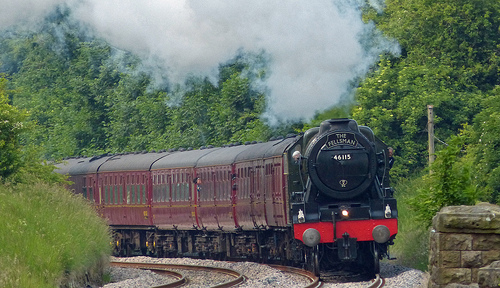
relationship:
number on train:
[334, 154, 339, 161] [42, 116, 397, 278]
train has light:
[42, 116, 397, 278] [337, 205, 353, 221]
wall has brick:
[428, 202, 500, 288] [482, 249, 499, 264]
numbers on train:
[329, 152, 357, 160] [68, 97, 420, 270]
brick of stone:
[438, 232, 473, 252] [433, 205, 499, 235]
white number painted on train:
[331, 149, 340, 161] [42, 116, 397, 278]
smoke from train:
[2, 0, 402, 130] [42, 116, 397, 278]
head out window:
[187, 170, 202, 185] [267, 158, 282, 178]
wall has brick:
[428, 202, 500, 288] [437, 232, 471, 249]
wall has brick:
[428, 202, 500, 288] [466, 233, 498, 249]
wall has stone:
[428, 202, 500, 288] [462, 250, 495, 265]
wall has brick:
[428, 202, 500, 288] [459, 250, 479, 266]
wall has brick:
[428, 202, 500, 288] [430, 212, 471, 230]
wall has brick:
[428, 202, 500, 288] [431, 267, 473, 284]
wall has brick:
[413, 190, 496, 286] [435, 229, 499, 282]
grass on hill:
[0, 184, 110, 285] [0, 74, 119, 287]